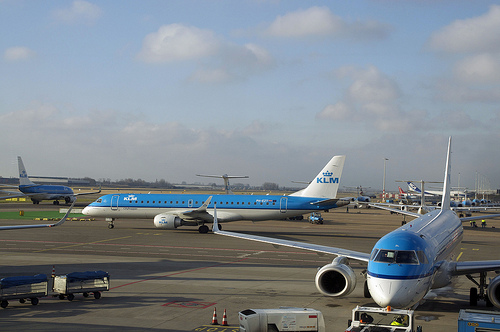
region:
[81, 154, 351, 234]
blue and white airplane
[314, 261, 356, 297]
large airplane engine under the wing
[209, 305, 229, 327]
orange and white cones on the ground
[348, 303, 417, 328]
two people in an airport vehicle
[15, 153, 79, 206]
airplane is on the runway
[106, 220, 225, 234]
landing gear is down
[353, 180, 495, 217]
line of several airplanes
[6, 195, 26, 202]
yellow signs on airport runway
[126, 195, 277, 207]
line of several passenger windows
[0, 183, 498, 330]
an airport's airfield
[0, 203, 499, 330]
an area of tarmac at the airport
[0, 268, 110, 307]
an airport cargo vehicle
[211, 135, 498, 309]
a passenger jet airplane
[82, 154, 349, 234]
a passenger jet airplane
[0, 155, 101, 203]
a passenger jet airplane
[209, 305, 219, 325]
an orange safety cone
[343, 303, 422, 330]
a white airport vehicle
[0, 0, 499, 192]
a large area of blue cloudy sky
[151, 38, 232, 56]
cloud in the sky.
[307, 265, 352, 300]
engine of the plane.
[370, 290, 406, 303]
nose of the plane.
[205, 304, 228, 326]
cones on the tarmac.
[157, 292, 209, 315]
red paint on the tarmac.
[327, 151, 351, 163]
tail of the plane.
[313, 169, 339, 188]
logo on the plane.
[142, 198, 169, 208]
windows on the plane.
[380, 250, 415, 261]
windshield on the plane.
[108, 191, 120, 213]
door of the plane.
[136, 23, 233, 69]
a cloud in the sky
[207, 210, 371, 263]
the wing of a plan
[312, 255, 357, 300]
the engine of a plane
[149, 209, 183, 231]
the engine of a plane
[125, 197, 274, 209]
the windows on the side of a plane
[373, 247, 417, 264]
the front window of a plane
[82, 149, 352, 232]
a blue and white plane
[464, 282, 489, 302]
the landing gear of a plane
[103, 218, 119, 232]
the landing gear of a plane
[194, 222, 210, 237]
the landing gear of a plane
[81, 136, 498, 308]
Airplanes parked on tarmac in service area.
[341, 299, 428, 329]
Service truck approaching plane.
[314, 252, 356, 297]
Jet engine mounted under plane's wing.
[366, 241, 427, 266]
Windows across cockpit area.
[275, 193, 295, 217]
Rear passenger door on side of plane.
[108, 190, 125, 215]
Front passenger door on side of plane.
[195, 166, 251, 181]
Rear horizontal stabilizer on plane.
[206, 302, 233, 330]
Orange and white traffic cones on tarmac.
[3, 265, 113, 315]
Luggage carts on tarmac.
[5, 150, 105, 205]
Plane taxiing out to runway.